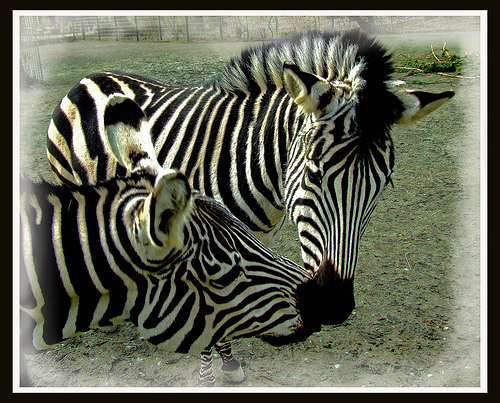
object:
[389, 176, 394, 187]
eyelashes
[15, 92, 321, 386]
zebras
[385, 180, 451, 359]
ground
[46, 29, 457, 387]
zebra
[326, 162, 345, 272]
stripes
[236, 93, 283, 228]
stripes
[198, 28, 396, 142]
hair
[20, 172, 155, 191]
hair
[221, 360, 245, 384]
feet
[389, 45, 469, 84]
grass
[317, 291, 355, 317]
nose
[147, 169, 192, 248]
ear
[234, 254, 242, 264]
eye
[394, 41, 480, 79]
branches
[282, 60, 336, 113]
ears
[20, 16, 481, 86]
fence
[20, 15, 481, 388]
yard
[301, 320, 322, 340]
noses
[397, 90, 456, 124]
ear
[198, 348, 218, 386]
legs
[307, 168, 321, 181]
eye